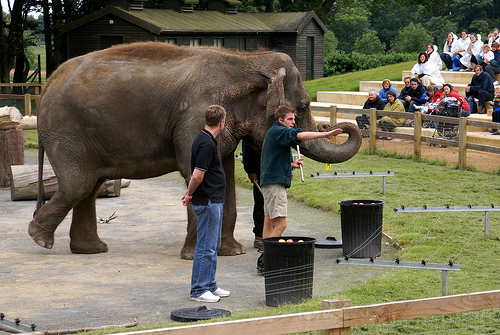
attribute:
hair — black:
[206, 103, 225, 125]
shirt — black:
[189, 127, 227, 206]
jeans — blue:
[190, 201, 221, 293]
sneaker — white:
[213, 286, 230, 297]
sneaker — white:
[191, 290, 220, 301]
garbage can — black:
[263, 235, 315, 305]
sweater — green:
[258, 120, 300, 189]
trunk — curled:
[288, 71, 361, 161]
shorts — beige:
[262, 184, 288, 218]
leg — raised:
[27, 96, 100, 247]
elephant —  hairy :
[28, 40, 361, 258]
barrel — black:
[339, 198, 383, 258]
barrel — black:
[261, 236, 314, 308]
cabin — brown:
[56, 0, 328, 81]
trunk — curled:
[292, 90, 362, 164]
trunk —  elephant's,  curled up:
[300, 120, 361, 163]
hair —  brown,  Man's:
[275, 104, 292, 121]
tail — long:
[29, 105, 49, 231]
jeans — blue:
[186, 215, 228, 311]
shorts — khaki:
[243, 172, 305, 242]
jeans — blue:
[191, 213, 214, 314]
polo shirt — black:
[186, 133, 232, 223]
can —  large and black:
[278, 258, 299, 279]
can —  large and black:
[350, 204, 376, 230]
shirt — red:
[453, 108, 469, 113]